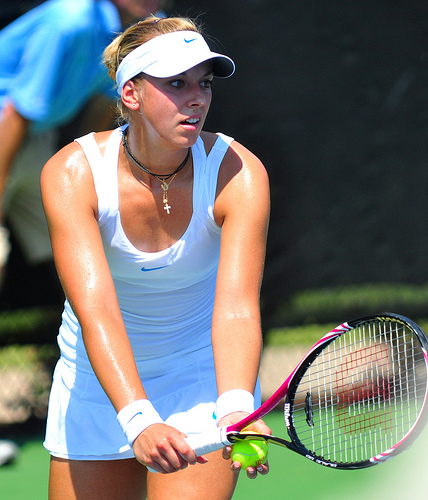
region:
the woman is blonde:
[27, 11, 293, 291]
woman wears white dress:
[14, 7, 420, 496]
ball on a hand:
[202, 391, 275, 477]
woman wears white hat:
[21, 8, 293, 497]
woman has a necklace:
[14, 6, 291, 289]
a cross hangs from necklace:
[159, 192, 176, 217]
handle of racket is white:
[134, 427, 240, 482]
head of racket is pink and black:
[279, 302, 427, 475]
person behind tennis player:
[3, 5, 257, 294]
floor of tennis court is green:
[5, 401, 427, 498]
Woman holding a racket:
[146, 309, 425, 471]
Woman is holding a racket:
[143, 307, 426, 476]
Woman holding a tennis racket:
[143, 298, 426, 472]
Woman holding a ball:
[228, 423, 273, 471]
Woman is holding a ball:
[224, 429, 280, 473]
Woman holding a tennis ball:
[227, 428, 268, 465]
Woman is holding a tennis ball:
[228, 426, 273, 468]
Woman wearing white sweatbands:
[113, 388, 261, 446]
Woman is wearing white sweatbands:
[110, 387, 263, 447]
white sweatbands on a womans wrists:
[105, 381, 259, 443]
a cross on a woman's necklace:
[162, 202, 172, 212]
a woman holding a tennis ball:
[225, 424, 273, 475]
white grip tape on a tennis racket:
[134, 419, 239, 480]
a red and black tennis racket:
[214, 303, 422, 486]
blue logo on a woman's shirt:
[138, 258, 165, 270]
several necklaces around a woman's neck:
[117, 132, 200, 211]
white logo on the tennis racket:
[280, 399, 290, 424]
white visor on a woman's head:
[109, 31, 230, 92]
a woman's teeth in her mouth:
[177, 110, 204, 132]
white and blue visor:
[115, 20, 235, 81]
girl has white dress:
[67, 89, 245, 445]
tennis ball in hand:
[233, 405, 265, 485]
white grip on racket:
[159, 395, 285, 461]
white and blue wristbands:
[112, 389, 154, 428]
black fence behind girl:
[264, 10, 416, 328]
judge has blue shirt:
[10, 0, 148, 105]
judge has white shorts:
[3, 82, 72, 246]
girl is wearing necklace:
[112, 136, 215, 231]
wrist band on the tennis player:
[112, 396, 163, 438]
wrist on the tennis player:
[214, 387, 251, 411]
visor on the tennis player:
[114, 31, 234, 83]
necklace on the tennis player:
[122, 149, 206, 218]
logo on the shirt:
[139, 258, 173, 275]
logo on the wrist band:
[125, 411, 142, 426]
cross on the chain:
[162, 203, 176, 214]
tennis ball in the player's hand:
[224, 431, 277, 476]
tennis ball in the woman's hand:
[228, 425, 272, 476]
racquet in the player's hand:
[134, 307, 424, 474]